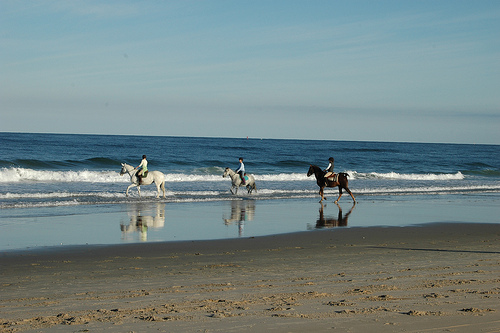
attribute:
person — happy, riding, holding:
[133, 154, 148, 187]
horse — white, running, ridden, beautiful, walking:
[120, 162, 168, 197]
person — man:
[235, 157, 246, 182]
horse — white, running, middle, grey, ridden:
[221, 167, 256, 195]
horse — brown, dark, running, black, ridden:
[306, 164, 357, 207]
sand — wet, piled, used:
[3, 225, 499, 331]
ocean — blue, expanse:
[0, 131, 499, 188]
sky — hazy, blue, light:
[3, 6, 497, 141]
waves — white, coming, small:
[4, 154, 469, 189]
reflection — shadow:
[308, 200, 356, 230]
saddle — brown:
[136, 170, 147, 185]